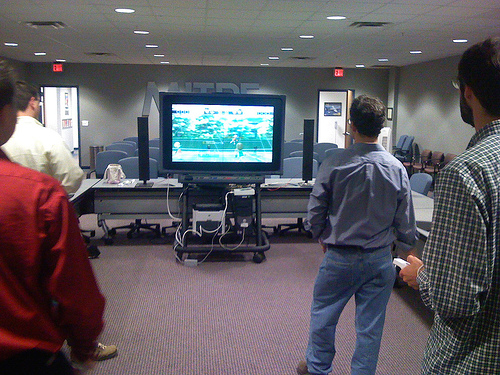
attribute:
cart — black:
[138, 157, 295, 301]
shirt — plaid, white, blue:
[412, 117, 498, 374]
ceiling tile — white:
[204, 5, 263, 22]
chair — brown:
[410, 157, 438, 203]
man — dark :
[299, 96, 417, 373]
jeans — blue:
[307, 245, 398, 370]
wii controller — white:
[387, 252, 409, 270]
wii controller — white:
[366, 247, 446, 289]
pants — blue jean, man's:
[305, 244, 395, 374]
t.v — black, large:
[153, 90, 278, 160]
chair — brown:
[422, 153, 446, 174]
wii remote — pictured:
[392, 255, 415, 272]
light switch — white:
[65, 109, 95, 131]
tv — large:
[157, 89, 292, 183]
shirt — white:
[1, 112, 84, 198]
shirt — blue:
[320, 142, 414, 257]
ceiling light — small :
[297, 30, 318, 45]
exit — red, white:
[325, 65, 353, 80]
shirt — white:
[11, 115, 68, 172]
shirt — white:
[23, 116, 80, 178]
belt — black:
[327, 234, 397, 252]